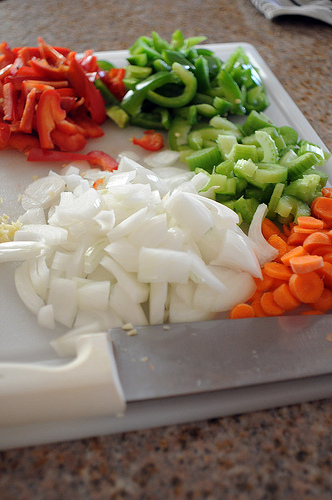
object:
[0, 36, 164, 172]
peppers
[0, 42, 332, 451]
board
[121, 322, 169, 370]
crumb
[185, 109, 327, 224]
celery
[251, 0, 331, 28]
book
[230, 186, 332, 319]
carrot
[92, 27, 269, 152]
green peppers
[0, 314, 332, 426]
knife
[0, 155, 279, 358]
onion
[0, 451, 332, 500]
counter top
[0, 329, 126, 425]
handle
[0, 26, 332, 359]
food